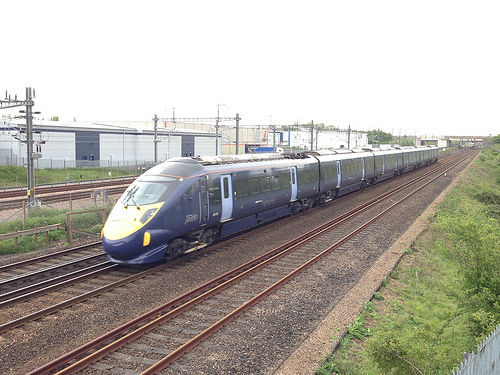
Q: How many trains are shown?
A: One.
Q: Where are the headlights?
A: On train.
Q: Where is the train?
A: On tracks.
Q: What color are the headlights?
A: Yellow.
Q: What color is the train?
A: Blue.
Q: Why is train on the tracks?
A: Traveling.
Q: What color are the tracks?
A: Brown.